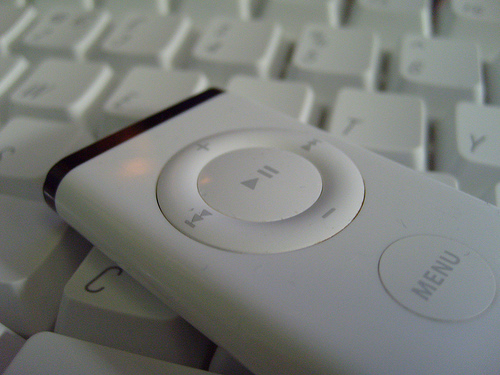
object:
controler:
[41, 83, 499, 373]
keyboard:
[0, 1, 496, 373]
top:
[42, 85, 225, 210]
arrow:
[300, 138, 322, 152]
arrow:
[184, 209, 213, 229]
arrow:
[240, 178, 259, 190]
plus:
[196, 141, 209, 151]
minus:
[322, 207, 336, 219]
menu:
[378, 234, 497, 321]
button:
[54, 244, 213, 370]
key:
[322, 85, 428, 172]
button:
[154, 126, 365, 254]